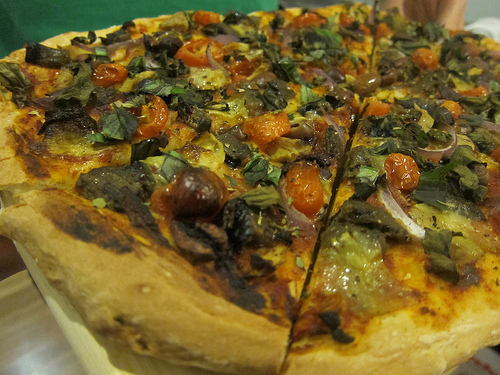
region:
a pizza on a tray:
[13, 102, 485, 374]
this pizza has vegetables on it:
[28, 27, 472, 359]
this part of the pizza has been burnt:
[60, 180, 293, 317]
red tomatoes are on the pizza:
[89, 30, 311, 147]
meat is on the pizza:
[353, 176, 434, 249]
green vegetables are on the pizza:
[91, 96, 278, 173]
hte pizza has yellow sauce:
[83, 125, 463, 330]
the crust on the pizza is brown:
[10, 195, 275, 364]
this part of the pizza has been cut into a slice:
[48, 72, 353, 357]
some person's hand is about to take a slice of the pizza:
[368, 2, 476, 55]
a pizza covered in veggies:
[0, 7, 498, 374]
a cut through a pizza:
[279, 106, 364, 361]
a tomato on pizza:
[282, 161, 334, 212]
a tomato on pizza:
[150, 164, 222, 219]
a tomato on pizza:
[133, 95, 168, 134]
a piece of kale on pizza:
[96, 104, 131, 139]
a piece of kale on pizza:
[245, 182, 280, 211]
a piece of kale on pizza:
[0, 60, 28, 105]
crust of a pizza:
[3, 185, 283, 374]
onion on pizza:
[375, 185, 425, 237]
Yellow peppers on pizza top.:
[250, 110, 290, 145]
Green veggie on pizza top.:
[102, 102, 132, 140]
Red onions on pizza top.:
[411, 126, 461, 158]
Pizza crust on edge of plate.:
[31, 195, 285, 373]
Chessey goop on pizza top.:
[330, 233, 407, 307]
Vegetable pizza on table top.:
[2, 2, 499, 374]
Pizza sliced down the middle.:
[285, 5, 372, 370]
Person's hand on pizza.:
[385, 0, 466, 30]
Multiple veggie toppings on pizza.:
[7, 8, 499, 308]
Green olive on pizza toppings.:
[351, 73, 378, 95]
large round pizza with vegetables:
[6, 0, 495, 371]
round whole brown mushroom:
[161, 156, 238, 218]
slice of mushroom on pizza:
[369, 181, 425, 250]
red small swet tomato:
[290, 155, 327, 221]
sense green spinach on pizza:
[225, 124, 295, 244]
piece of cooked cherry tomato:
[247, 105, 301, 152]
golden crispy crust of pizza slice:
[5, 185, 291, 373]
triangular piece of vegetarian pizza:
[11, 91, 371, 373]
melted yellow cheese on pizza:
[5, 20, 499, 355]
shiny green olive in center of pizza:
[349, 70, 385, 95]